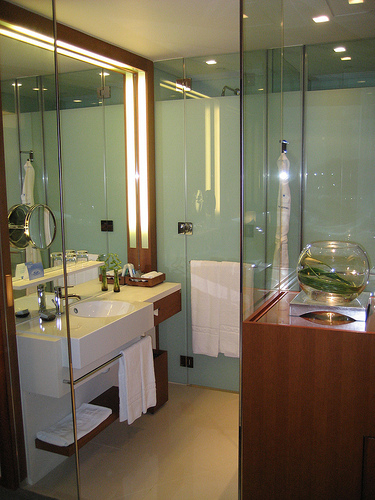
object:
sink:
[69, 300, 131, 319]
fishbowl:
[297, 240, 371, 306]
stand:
[238, 291, 374, 500]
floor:
[33, 386, 239, 497]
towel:
[190, 259, 253, 357]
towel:
[118, 335, 156, 426]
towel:
[35, 402, 112, 448]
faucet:
[52, 286, 81, 314]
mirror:
[0, 26, 128, 325]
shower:
[241, 0, 375, 319]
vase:
[113, 272, 120, 293]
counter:
[16, 282, 181, 398]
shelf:
[34, 385, 119, 458]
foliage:
[298, 266, 360, 293]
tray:
[125, 273, 166, 287]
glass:
[65, 250, 77, 265]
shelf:
[11, 261, 105, 291]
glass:
[77, 250, 88, 265]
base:
[289, 290, 371, 321]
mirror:
[28, 205, 56, 250]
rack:
[63, 354, 122, 385]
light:
[125, 69, 148, 249]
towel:
[276, 152, 290, 292]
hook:
[282, 140, 287, 154]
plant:
[109, 251, 122, 270]